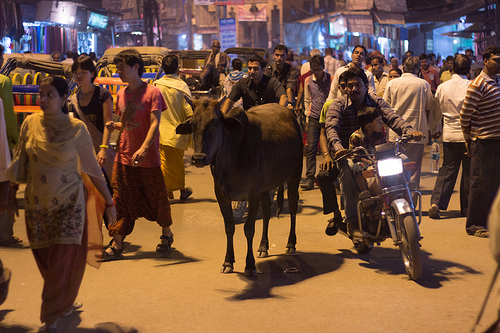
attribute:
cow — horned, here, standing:
[175, 79, 247, 118]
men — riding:
[322, 75, 379, 99]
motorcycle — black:
[324, 127, 429, 204]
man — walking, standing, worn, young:
[107, 47, 177, 160]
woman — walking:
[31, 81, 88, 170]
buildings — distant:
[103, 2, 365, 53]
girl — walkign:
[28, 83, 112, 189]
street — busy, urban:
[120, 202, 358, 327]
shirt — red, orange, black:
[114, 89, 215, 171]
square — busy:
[71, 36, 489, 230]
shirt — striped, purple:
[453, 60, 490, 103]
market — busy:
[77, 28, 421, 157]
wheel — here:
[395, 216, 442, 269]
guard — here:
[4, 71, 59, 212]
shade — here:
[265, 242, 357, 323]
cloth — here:
[83, 204, 128, 253]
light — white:
[364, 150, 399, 170]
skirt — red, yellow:
[24, 243, 89, 297]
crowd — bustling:
[113, 35, 393, 140]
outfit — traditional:
[26, 114, 113, 264]